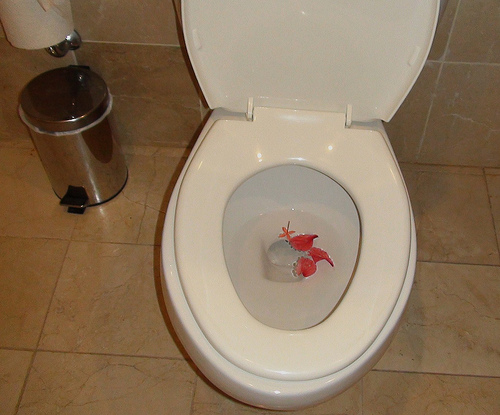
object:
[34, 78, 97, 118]
trash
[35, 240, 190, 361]
floor tile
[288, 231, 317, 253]
red leaf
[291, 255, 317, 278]
red leaf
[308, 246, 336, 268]
red leaf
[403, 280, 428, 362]
shadow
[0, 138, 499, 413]
floor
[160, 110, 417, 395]
toilet bowl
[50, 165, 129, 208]
bottom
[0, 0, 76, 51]
toilet paper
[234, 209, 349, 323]
water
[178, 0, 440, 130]
lid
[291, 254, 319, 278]
flower petals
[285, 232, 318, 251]
petals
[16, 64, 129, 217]
can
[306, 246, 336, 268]
petals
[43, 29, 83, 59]
holder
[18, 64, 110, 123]
garbage bag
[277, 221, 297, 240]
leaf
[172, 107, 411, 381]
seat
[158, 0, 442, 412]
toilet